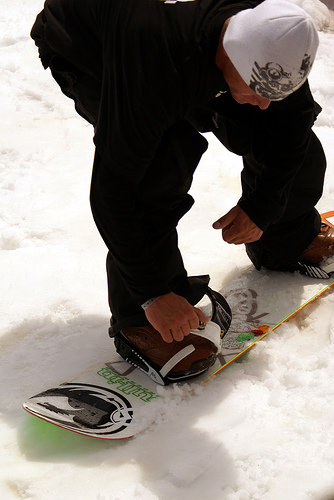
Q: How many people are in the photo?
A: One.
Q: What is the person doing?
A: Strapping on skis.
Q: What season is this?
A: Winter.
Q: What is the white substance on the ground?
A: Snow.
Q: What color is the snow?
A: White.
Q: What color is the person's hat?
A: White.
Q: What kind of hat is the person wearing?
A: Knit hat.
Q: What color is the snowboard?
A: White , black, grey and green.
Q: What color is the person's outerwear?
A: Black.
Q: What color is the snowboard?
A: White.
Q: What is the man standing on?
A: A snowboard.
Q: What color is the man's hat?
A: White.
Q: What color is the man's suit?
A: Black.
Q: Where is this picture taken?
A: A snow slope.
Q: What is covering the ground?
A: Snow.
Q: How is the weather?
A: Sunny.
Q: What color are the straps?
A: White.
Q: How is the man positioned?
A: Bent over.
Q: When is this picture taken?
A: Afternoon.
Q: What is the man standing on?
A: Snowboard.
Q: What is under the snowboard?
A: Snow.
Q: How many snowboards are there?
A: 1.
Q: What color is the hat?
A: White.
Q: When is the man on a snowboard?
A: Winter day.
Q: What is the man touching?
A: Bootstrap.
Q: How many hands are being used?
A: 1.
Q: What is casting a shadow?
A: Snowboarder.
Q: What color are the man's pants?
A: Black.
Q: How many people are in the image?
A: 1.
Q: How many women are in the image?
A: 0.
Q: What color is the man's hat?
A: White.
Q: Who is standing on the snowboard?
A: The man.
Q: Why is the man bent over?
A: To tighten his boot.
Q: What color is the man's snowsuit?
A: Black.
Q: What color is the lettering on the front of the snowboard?
A: Green.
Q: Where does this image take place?
A: At a ski resort.